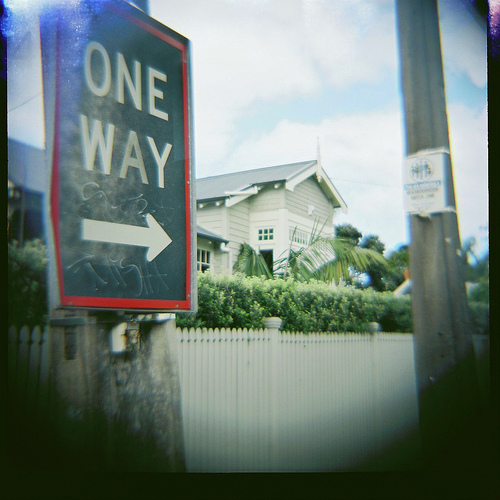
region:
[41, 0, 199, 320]
thats a one way sign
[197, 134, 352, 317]
thats a white house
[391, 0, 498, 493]
this is a telephone pole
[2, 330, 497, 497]
this is a white fence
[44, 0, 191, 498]
this is a telephone pole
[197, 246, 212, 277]
thats a window pane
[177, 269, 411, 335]
these are some bushes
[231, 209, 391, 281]
these are long plants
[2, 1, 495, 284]
this is the blue sky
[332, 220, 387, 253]
these are two trees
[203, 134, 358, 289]
a big white house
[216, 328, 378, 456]
a long white fence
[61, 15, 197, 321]
one way sign hanging on a tree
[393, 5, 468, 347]
an electrical post on the street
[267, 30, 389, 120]
big white clouds in the sky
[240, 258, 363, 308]
the green plants in front of the house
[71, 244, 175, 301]
there are some writings in the sign board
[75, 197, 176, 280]
an arrow facing to the house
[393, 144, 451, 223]
a white poster on the electrical post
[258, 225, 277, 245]
some square holes in the house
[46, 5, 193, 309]
the traffic sign on the concrete post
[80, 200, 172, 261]
the arrow on the sign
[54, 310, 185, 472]
the concrete post for the sign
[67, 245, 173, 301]
the letters on the sign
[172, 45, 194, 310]
the red outline on the street sign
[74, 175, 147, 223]
the white graffitti on the street sign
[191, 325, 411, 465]
the white pickett fence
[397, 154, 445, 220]
the white sign on the post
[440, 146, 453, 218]
the brackets around the pole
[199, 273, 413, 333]
the bushes behind the fence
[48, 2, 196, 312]
A green "One Way" street sign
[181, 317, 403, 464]
A segment of white fencing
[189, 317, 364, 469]
A segment of white picket fence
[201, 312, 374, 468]
A portion of white picket fencing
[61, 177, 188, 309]
White graffiti written on a traffic sign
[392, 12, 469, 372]
A telephone pole with an advertisement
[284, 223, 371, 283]
Portion of a palm tree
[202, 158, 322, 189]
Portion of house roofing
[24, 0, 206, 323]
A green street sign with white graffiti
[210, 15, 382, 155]
Cumulus clouds against a pale blue sky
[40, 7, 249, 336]
this is a one-way sign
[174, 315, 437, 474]
this is a white fence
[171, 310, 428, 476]
a wooden fence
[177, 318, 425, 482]
a white picket fence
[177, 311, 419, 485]
a fence painted white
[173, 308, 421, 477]
a white washed fence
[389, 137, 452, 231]
this sign is on a cement post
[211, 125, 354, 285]
the gable of a house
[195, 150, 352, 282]
this is a house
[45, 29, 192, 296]
there is graffiti on the sign